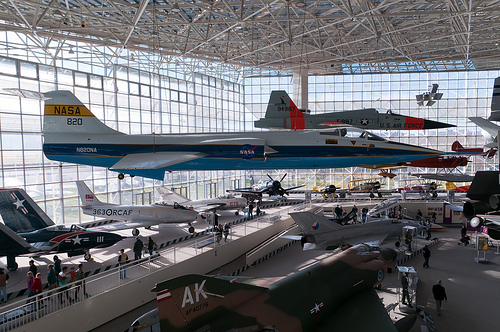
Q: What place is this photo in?
A: It is at the museum.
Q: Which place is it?
A: It is a museum.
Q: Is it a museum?
A: Yes, it is a museum.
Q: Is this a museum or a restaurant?
A: It is a museum.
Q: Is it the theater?
A: No, it is the museum.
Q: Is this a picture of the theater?
A: No, the picture is showing the museum.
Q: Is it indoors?
A: Yes, it is indoors.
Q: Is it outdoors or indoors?
A: It is indoors.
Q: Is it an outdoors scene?
A: No, it is indoors.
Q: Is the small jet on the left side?
A: Yes, the jet is on the left of the image.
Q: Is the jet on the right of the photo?
A: No, the jet is on the left of the image.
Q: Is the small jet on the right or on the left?
A: The jet is on the left of the image.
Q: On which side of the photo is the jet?
A: The jet is on the left of the image.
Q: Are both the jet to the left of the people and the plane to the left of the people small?
A: Yes, both the jet and the plane are small.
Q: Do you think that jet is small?
A: Yes, the jet is small.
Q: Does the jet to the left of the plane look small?
A: Yes, the jet is small.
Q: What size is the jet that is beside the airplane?
A: The jet is small.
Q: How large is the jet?
A: The jet is small.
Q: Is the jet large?
A: No, the jet is small.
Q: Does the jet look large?
A: No, the jet is small.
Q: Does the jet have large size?
A: No, the jet is small.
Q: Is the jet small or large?
A: The jet is small.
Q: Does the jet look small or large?
A: The jet is small.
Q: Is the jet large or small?
A: The jet is small.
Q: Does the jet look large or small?
A: The jet is small.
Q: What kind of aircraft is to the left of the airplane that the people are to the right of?
A: The aircraft is a jet.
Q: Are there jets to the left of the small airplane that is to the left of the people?
A: Yes, there is a jet to the left of the plane.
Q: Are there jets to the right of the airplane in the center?
A: No, the jet is to the left of the airplane.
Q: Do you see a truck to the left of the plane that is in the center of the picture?
A: No, there is a jet to the left of the airplane.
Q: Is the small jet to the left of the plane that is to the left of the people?
A: Yes, the jet is to the left of the airplane.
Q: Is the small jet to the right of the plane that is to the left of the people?
A: No, the jet is to the left of the airplane.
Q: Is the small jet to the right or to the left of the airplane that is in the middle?
A: The jet is to the left of the plane.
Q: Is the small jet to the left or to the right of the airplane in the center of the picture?
A: The jet is to the left of the plane.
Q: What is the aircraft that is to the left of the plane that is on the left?
A: The aircraft is a jet.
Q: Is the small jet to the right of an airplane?
A: No, the jet is to the left of an airplane.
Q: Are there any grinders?
A: No, there are no grinders.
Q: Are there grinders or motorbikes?
A: No, there are no grinders or motorbikes.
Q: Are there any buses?
A: No, there are no buses.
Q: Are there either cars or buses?
A: No, there are no buses or cars.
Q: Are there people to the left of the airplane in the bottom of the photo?
A: Yes, there are people to the left of the plane.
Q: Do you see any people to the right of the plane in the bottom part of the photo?
A: No, the people are to the left of the plane.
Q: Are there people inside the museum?
A: Yes, there are people inside the museum.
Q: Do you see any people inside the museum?
A: Yes, there are people inside the museum.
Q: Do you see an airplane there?
A: Yes, there is an airplane.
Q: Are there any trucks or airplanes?
A: Yes, there is an airplane.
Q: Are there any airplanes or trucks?
A: Yes, there is an airplane.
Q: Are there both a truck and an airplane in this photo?
A: No, there is an airplane but no trucks.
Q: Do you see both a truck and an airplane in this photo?
A: No, there is an airplane but no trucks.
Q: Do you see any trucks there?
A: No, there are no trucks.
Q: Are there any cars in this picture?
A: No, there are no cars.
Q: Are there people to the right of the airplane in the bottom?
A: Yes, there is a person to the right of the airplane.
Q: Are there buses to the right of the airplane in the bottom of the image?
A: No, there is a person to the right of the airplane.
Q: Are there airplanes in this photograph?
A: Yes, there is an airplane.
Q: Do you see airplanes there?
A: Yes, there is an airplane.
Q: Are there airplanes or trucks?
A: Yes, there is an airplane.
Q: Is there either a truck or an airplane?
A: Yes, there is an airplane.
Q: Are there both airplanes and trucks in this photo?
A: No, there is an airplane but no trucks.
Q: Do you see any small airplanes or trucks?
A: Yes, there is a small airplane.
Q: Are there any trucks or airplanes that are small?
A: Yes, the airplane is small.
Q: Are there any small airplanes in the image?
A: Yes, there is a small airplane.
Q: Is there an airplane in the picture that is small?
A: Yes, there is an airplane that is small.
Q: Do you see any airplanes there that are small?
A: Yes, there is an airplane that is small.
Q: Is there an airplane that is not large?
A: Yes, there is a small airplane.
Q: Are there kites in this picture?
A: No, there are no kites.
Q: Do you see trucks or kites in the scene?
A: No, there are no kites or trucks.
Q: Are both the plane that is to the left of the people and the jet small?
A: Yes, both the plane and the jet are small.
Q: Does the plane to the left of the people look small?
A: Yes, the airplane is small.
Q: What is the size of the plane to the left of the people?
A: The airplane is small.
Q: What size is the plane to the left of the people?
A: The airplane is small.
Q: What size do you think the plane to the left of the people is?
A: The airplane is small.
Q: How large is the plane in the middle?
A: The airplane is small.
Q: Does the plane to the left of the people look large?
A: No, the plane is small.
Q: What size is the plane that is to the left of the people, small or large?
A: The plane is small.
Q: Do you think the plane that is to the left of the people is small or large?
A: The plane is small.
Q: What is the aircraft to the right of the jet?
A: The aircraft is an airplane.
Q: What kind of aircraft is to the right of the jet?
A: The aircraft is an airplane.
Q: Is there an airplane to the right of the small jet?
A: Yes, there is an airplane to the right of the jet.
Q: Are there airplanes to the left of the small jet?
A: No, the airplane is to the right of the jet.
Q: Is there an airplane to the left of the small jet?
A: No, the airplane is to the right of the jet.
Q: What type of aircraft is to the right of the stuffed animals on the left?
A: The aircraft is an airplane.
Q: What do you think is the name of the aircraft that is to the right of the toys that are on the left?
A: The aircraft is an airplane.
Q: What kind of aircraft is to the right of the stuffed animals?
A: The aircraft is an airplane.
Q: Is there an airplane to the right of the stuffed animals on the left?
A: Yes, there is an airplane to the right of the stuffed animals.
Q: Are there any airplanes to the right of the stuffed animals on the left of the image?
A: Yes, there is an airplane to the right of the stuffed animals.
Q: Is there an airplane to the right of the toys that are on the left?
A: Yes, there is an airplane to the right of the stuffed animals.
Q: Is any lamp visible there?
A: No, there are no lamps.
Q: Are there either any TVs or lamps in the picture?
A: No, there are no lamps or tvs.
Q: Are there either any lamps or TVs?
A: No, there are no lamps or tvs.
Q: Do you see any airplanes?
A: Yes, there is an airplane.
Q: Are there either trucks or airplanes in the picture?
A: Yes, there is an airplane.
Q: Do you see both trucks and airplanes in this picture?
A: No, there is an airplane but no trucks.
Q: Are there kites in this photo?
A: No, there are no kites.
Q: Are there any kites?
A: No, there are no kites.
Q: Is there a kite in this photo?
A: No, there are no kites.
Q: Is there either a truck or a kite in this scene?
A: No, there are no kites or trucks.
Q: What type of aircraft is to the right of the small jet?
A: The aircraft is an airplane.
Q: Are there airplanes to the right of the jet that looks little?
A: Yes, there is an airplane to the right of the jet.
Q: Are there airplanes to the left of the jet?
A: No, the airplane is to the right of the jet.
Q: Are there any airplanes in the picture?
A: Yes, there is an airplane.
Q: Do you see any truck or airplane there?
A: Yes, there is an airplane.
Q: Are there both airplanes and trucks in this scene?
A: No, there is an airplane but no trucks.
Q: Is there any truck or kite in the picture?
A: No, there are no kites or trucks.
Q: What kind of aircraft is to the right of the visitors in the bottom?
A: The aircraft is an airplane.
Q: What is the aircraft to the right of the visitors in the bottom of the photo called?
A: The aircraft is an airplane.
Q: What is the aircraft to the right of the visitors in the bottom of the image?
A: The aircraft is an airplane.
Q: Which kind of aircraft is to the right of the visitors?
A: The aircraft is an airplane.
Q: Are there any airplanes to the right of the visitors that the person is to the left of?
A: Yes, there is an airplane to the right of the visitors.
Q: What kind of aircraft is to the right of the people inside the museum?
A: The aircraft is an airplane.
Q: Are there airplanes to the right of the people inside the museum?
A: Yes, there is an airplane to the right of the people.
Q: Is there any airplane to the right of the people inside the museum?
A: Yes, there is an airplane to the right of the people.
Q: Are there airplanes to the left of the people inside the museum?
A: No, the airplane is to the right of the people.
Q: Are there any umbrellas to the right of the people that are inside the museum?
A: No, there is an airplane to the right of the people.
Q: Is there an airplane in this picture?
A: Yes, there is an airplane.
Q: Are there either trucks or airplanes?
A: Yes, there is an airplane.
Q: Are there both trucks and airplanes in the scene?
A: No, there is an airplane but no trucks.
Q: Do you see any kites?
A: No, there are no kites.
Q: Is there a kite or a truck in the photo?
A: No, there are no kites or trucks.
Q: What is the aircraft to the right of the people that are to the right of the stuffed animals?
A: The aircraft is an airplane.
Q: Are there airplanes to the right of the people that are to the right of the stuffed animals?
A: Yes, there is an airplane to the right of the people.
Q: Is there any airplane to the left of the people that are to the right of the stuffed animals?
A: No, the airplane is to the right of the people.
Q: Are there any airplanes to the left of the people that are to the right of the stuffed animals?
A: No, the airplane is to the right of the people.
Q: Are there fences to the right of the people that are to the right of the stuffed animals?
A: No, there is an airplane to the right of the people.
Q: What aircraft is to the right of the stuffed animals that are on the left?
A: The aircraft is an airplane.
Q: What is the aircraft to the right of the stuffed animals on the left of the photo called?
A: The aircraft is an airplane.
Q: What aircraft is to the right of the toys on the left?
A: The aircraft is an airplane.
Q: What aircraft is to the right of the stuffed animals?
A: The aircraft is an airplane.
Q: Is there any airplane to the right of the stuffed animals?
A: Yes, there is an airplane to the right of the stuffed animals.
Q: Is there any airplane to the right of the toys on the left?
A: Yes, there is an airplane to the right of the stuffed animals.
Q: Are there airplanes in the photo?
A: Yes, there is an airplane.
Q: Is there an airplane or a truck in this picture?
A: Yes, there is an airplane.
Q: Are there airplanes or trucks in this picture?
A: Yes, there is an airplane.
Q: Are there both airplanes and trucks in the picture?
A: No, there is an airplane but no trucks.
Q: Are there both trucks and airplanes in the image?
A: No, there is an airplane but no trucks.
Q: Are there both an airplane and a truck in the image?
A: No, there is an airplane but no trucks.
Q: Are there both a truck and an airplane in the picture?
A: No, there is an airplane but no trucks.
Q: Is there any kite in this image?
A: No, there are no kites.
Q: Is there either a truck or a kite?
A: No, there are no kites or trucks.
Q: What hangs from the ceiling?
A: The plane hangs from the ceiling.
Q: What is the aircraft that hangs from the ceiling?
A: The aircraft is an airplane.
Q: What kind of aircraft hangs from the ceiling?
A: The aircraft is an airplane.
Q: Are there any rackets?
A: No, there are no rackets.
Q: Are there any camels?
A: No, there are no camels.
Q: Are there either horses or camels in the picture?
A: No, there are no camels or horses.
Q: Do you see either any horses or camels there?
A: No, there are no camels or horses.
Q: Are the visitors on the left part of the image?
A: Yes, the visitors are on the left of the image.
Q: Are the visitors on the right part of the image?
A: No, the visitors are on the left of the image.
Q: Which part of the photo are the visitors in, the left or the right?
A: The visitors are on the left of the image.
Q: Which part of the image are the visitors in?
A: The visitors are on the left of the image.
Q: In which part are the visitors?
A: The visitors are on the left of the image.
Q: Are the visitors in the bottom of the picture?
A: Yes, the visitors are in the bottom of the image.